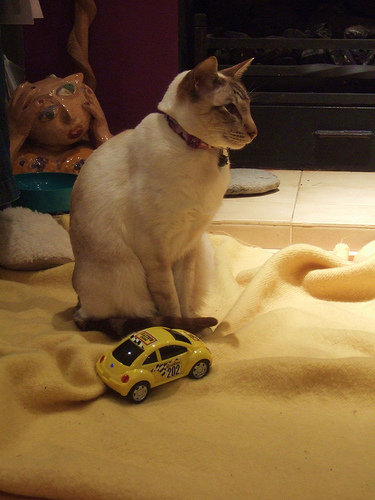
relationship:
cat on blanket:
[67, 54, 258, 335] [1, 237, 372, 498]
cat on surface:
[67, 54, 258, 335] [1, 237, 372, 498]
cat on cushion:
[67, 54, 258, 335] [1, 237, 372, 498]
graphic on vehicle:
[152, 362, 165, 380] [95, 323, 212, 407]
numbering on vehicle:
[165, 363, 180, 379] [95, 323, 212, 407]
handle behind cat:
[312, 127, 372, 143] [67, 54, 258, 335]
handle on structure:
[312, 127, 372, 143] [185, 7, 374, 166]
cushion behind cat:
[1, 237, 372, 498] [67, 54, 258, 335]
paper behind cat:
[0, 3, 47, 32] [67, 54, 258, 335]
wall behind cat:
[21, 1, 183, 139] [67, 54, 258, 335]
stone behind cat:
[217, 166, 284, 196] [67, 54, 258, 335]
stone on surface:
[217, 166, 284, 196] [209, 160, 374, 222]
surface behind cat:
[209, 160, 374, 222] [67, 54, 258, 335]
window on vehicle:
[156, 342, 189, 360] [95, 323, 212, 407]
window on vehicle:
[141, 349, 158, 367] [95, 323, 212, 407]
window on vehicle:
[163, 325, 197, 347] [95, 323, 212, 407]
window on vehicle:
[110, 338, 144, 368] [95, 323, 212, 407]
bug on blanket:
[95, 323, 212, 407] [1, 237, 372, 498]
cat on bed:
[67, 54, 258, 335] [1, 237, 372, 498]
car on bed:
[95, 323, 212, 407] [1, 237, 372, 498]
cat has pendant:
[67, 54, 258, 335] [213, 145, 231, 170]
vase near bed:
[8, 73, 114, 181] [1, 237, 372, 498]